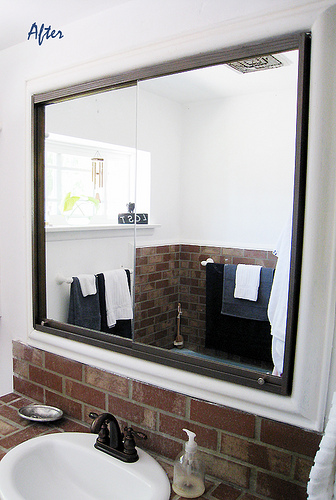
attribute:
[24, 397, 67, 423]
soap dish — empty, silver, metal, white, stainless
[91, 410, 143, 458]
faucet — black, brown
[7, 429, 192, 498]
sink — white, clean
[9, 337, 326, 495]
wall — brick, red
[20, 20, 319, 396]
mirror — reflecting, dark, large, white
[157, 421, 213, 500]
soap bottle — plastic, empty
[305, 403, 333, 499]
towels — hanging, white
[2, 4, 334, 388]
wall — white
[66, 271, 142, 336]
towels — hanging, blue, black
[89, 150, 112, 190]
chime — hanging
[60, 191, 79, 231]
plant — small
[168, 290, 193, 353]
brush — long